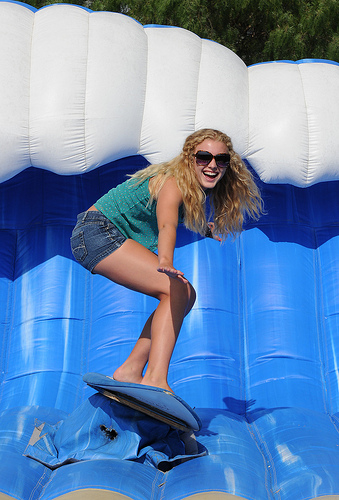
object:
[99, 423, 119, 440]
tear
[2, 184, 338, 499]
covering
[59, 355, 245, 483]
platform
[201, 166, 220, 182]
smile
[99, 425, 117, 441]
rip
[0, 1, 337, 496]
tarp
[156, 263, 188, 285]
fingers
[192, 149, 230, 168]
sunglasses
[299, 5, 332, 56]
tree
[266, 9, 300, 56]
tree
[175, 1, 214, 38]
tree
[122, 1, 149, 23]
tree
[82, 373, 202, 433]
surfboard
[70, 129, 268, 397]
girl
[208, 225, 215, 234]
ring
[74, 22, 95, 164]
seam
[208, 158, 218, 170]
nose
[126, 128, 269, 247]
blonde hair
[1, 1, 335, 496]
inflatable waves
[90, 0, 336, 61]
tree leaves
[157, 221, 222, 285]
hands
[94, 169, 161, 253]
shirt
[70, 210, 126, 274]
shorts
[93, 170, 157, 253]
tank top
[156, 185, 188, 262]
arm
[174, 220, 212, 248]
arm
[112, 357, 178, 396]
bare feet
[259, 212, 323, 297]
inflatable pads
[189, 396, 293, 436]
shadow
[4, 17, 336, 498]
pad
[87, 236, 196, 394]
legs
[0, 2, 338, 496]
inflatable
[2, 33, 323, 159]
material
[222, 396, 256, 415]
bird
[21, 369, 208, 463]
simulator